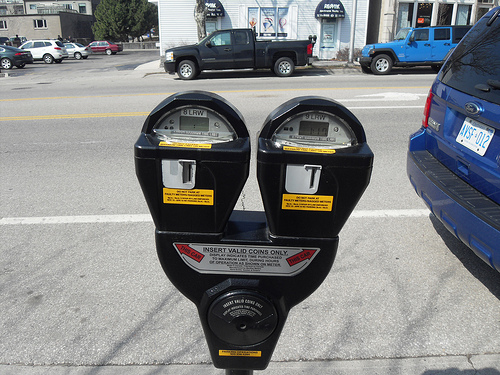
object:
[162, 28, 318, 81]
truck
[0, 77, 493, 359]
street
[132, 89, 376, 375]
meter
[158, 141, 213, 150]
sticker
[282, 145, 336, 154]
sticker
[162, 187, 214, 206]
sticker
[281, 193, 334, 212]
sticker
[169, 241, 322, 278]
sticker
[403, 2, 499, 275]
ford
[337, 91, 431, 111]
arrow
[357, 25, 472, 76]
car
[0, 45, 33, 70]
car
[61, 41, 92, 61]
car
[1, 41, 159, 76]
lot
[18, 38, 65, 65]
car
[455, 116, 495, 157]
plate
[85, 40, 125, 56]
vehicle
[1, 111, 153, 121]
line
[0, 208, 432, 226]
line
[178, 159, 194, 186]
slot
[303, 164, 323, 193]
slot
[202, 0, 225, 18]
awning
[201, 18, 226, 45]
door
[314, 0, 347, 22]
awning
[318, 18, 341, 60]
door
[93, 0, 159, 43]
tree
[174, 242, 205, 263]
arrow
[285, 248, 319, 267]
arrow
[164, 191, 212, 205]
writing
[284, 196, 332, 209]
writing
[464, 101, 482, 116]
symbol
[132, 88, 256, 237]
meter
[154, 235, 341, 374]
stand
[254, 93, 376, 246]
meter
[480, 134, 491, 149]
number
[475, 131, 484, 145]
number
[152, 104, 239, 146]
face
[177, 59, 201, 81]
tire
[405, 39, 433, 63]
door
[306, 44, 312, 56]
light